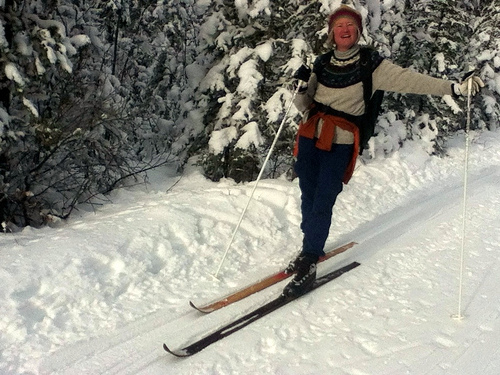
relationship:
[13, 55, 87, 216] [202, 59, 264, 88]
trees covered in snow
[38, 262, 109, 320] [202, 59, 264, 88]
tracks in snow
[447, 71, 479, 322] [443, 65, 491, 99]
ski pole in hand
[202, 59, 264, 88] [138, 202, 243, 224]
snow on ground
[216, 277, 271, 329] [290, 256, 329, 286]
skis on boots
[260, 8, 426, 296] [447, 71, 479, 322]
woman holding ski pole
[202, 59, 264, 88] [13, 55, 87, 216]
snow on trees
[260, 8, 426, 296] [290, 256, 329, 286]
woman wearing boots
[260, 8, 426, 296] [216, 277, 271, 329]
woman holding skis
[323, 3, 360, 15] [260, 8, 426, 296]
hat on woman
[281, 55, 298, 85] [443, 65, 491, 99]
glove on hand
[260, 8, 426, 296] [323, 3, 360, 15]
woman wearing hat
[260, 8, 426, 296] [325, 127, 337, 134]
woman wearing sweater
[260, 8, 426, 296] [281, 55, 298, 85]
woman wearing glove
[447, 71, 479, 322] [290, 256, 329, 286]
ski pole on boots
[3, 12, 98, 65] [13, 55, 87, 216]
branches of trees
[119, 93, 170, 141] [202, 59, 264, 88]
path in snow